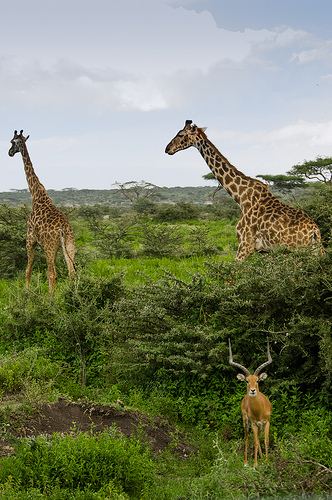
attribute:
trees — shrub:
[16, 232, 330, 400]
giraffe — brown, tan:
[164, 119, 325, 265]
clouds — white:
[7, 33, 35, 101]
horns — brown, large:
[187, 123, 206, 134]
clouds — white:
[0, 2, 330, 191]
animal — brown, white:
[222, 330, 298, 481]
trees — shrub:
[248, 139, 331, 218]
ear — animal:
[257, 371, 267, 381]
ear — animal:
[236, 372, 246, 382]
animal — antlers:
[226, 338, 272, 468]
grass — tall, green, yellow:
[139, 375, 238, 434]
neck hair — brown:
[185, 119, 269, 187]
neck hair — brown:
[23, 138, 48, 194]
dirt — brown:
[16, 406, 180, 452]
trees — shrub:
[74, 271, 322, 360]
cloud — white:
[62, 73, 166, 122]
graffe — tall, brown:
[155, 110, 327, 281]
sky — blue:
[0, 0, 327, 180]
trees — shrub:
[132, 214, 187, 261]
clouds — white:
[239, 51, 282, 99]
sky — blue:
[1, 1, 331, 115]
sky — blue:
[10, 13, 325, 102]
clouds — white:
[36, 30, 115, 80]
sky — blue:
[27, 28, 329, 125]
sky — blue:
[30, 20, 325, 113]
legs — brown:
[246, 426, 265, 451]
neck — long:
[23, 164, 39, 199]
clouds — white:
[13, 12, 46, 35]